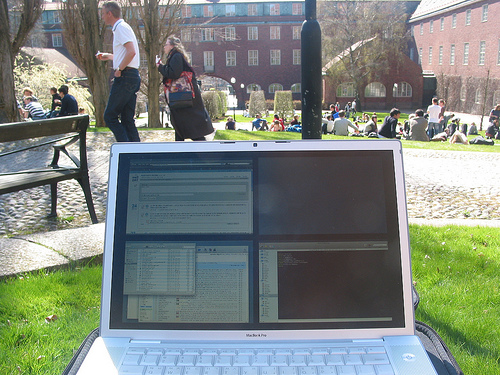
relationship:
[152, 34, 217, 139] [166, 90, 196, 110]
woman carrying bag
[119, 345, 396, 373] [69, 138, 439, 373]
keyboard on laptop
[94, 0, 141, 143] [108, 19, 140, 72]
man with shirt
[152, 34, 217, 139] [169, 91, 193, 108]
woman with bag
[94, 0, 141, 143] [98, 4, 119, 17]
man has grey hair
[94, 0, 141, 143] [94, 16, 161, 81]
man has shirt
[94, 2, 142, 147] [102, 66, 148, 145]
man has blue pants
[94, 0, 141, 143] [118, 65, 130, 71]
man wears watch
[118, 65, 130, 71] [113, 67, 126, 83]
watch on hand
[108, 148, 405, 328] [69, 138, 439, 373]
screen on laptop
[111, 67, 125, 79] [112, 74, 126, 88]
hand in pocket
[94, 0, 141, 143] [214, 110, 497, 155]
man sit on grass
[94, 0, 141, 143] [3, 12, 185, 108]
man sit next to tree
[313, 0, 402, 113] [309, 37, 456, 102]
tree in front of building